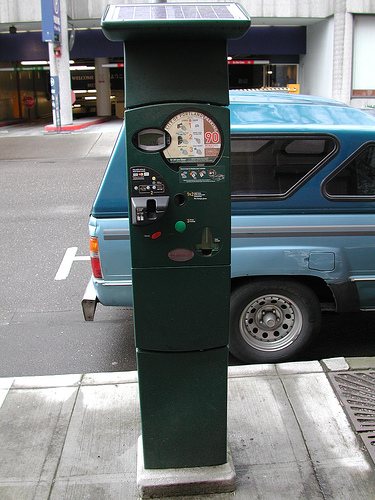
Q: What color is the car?
A: Blue.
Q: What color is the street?
A: Gray.